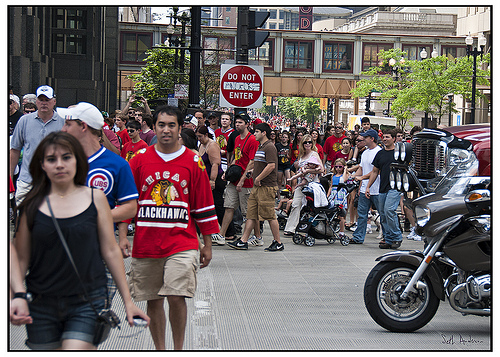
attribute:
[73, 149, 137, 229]
jersey — blue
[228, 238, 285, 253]
shoes — black